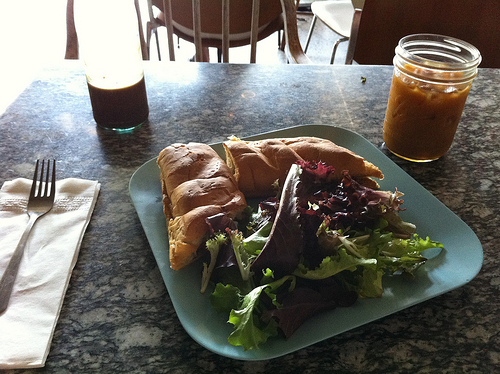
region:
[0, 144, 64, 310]
A clean silver fork.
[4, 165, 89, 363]
An unused white folded napkin.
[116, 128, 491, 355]
A square white plate with round edges.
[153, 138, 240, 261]
half of a bread sandwich.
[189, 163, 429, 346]
An assortment of leafy greens.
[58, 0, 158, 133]
A container with salad dressing in it.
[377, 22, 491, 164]
A glass jar filled with a beverage.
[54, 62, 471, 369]
A table with a meal on it.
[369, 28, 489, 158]
this beverage has ice in it.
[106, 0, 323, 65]
the backing of a chair by the table.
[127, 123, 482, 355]
sandwich and salad on a plate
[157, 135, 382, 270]
sandwich cut in half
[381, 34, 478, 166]
a iced drink in a jar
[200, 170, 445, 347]
a salad with green and purple lettuce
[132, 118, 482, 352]
a light blue square plate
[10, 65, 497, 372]
a table with a gray granite top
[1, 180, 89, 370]
a white paper napkin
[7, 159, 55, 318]
a metal fork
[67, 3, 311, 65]
a wooden chair on other side of table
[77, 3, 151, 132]
half-full bottle on the left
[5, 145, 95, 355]
An unused silver fork.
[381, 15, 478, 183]
A jar full with a beverage.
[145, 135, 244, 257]
A half piece of a sandwich.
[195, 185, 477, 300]
An assorted green salad.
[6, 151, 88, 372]
An unused white napkin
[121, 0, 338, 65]
The backing of a chair next to the table.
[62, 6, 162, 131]
A container with salad dressing.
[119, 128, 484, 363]
A square white plate with rounded edges.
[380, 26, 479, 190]
This beverage has ice in it.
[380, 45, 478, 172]
small jar of dressing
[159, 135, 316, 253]
sliced bread on plate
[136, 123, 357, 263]
bread is light brown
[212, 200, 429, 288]
green and purple lettuce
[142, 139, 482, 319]
green plate on table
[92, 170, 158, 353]
table is light grey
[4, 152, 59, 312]
fork on white napkin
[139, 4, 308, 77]
white chair across table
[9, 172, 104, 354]
napkin on grey table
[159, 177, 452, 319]
undressed salad on plate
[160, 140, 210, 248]
sandwich on a plate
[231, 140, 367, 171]
sandwich on a plate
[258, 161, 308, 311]
lettuce on a plate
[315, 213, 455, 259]
lettuce on a plate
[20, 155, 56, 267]
fork on a napkin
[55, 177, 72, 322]
napkin on a table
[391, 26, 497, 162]
jar on a table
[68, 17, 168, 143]
glass on a table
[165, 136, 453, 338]
food on a plate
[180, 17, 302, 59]
chair next to table